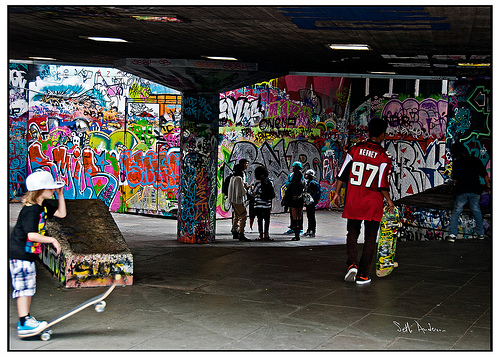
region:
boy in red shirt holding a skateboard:
[335, 109, 422, 286]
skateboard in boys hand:
[379, 196, 402, 286]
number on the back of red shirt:
[347, 157, 382, 197]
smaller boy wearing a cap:
[7, 162, 84, 221]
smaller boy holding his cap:
[19, 166, 95, 244]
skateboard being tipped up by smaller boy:
[22, 277, 168, 352]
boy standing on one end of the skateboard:
[12, 171, 58, 343]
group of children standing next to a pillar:
[227, 141, 327, 258]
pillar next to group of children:
[139, 62, 238, 245]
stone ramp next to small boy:
[42, 183, 163, 318]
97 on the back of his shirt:
[332, 150, 411, 210]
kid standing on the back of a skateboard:
[6, 158, 116, 342]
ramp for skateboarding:
[35, 182, 173, 300]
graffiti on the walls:
[30, 81, 187, 210]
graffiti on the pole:
[172, 88, 266, 275]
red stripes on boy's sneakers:
[334, 250, 386, 296]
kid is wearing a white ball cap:
[21, 163, 78, 214]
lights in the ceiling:
[23, 35, 374, 66]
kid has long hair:
[18, 171, 99, 223]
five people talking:
[203, 155, 349, 267]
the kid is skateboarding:
[23, 156, 164, 348]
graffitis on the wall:
[15, 72, 296, 216]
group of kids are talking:
[223, 140, 331, 223]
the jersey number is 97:
[317, 118, 374, 231]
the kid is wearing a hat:
[18, 162, 115, 242]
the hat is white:
[20, 162, 100, 215]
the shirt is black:
[10, 197, 53, 285]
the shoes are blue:
[8, 307, 80, 333]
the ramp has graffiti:
[43, 186, 220, 312]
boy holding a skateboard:
[313, 107, 402, 301]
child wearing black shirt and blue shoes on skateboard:
[12, 164, 122, 346]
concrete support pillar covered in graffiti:
[114, 46, 287, 248]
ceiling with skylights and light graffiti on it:
[7, 3, 497, 84]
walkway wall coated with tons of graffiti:
[6, 54, 496, 243]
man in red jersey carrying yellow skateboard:
[332, 109, 407, 300]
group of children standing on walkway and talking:
[220, 148, 330, 248]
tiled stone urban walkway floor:
[8, 189, 488, 347]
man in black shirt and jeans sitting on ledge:
[441, 139, 492, 243]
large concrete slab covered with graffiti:
[28, 187, 140, 290]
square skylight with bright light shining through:
[322, 39, 377, 60]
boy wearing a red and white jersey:
[336, 132, 395, 217]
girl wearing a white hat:
[21, 163, 68, 190]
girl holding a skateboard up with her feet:
[13, 277, 130, 341]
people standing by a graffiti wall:
[228, 150, 330, 243]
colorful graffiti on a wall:
[36, 67, 172, 162]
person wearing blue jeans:
[448, 191, 491, 236]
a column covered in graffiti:
[176, 78, 223, 250]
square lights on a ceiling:
[85, 30, 376, 65]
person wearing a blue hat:
[287, 159, 304, 170]